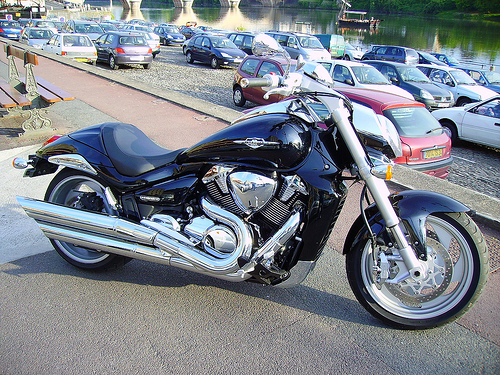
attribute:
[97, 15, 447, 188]
cars — parked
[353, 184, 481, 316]
tire — see, black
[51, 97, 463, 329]
bike — black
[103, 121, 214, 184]
seat — black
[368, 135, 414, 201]
headlight — yellow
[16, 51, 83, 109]
bench — see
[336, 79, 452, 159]
car — red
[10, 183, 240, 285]
pipes — silver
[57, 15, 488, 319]
motorcycle — black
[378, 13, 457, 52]
water — gree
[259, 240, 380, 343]
shade — see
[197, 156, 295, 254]
metal — see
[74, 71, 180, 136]
road — see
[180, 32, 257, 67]
car — blue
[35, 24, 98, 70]
car — white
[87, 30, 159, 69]
car — violet